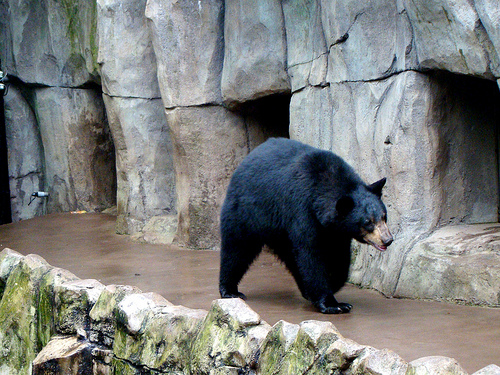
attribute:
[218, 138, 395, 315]
bear — black, walking, furry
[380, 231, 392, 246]
nose — black, brown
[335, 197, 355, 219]
ear — black, pointy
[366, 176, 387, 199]
ear — black, pointy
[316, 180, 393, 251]
head — black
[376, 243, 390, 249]
tongue — pink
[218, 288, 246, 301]
paw — black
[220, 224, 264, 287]
leg — black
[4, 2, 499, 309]
wall — rock, gray, large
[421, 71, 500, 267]
cave — rock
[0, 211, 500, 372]
pathway — concrete, brown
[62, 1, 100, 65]
moss — growing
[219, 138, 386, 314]
fur — black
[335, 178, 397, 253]
face — lightly colored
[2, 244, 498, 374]
wall — green, gray